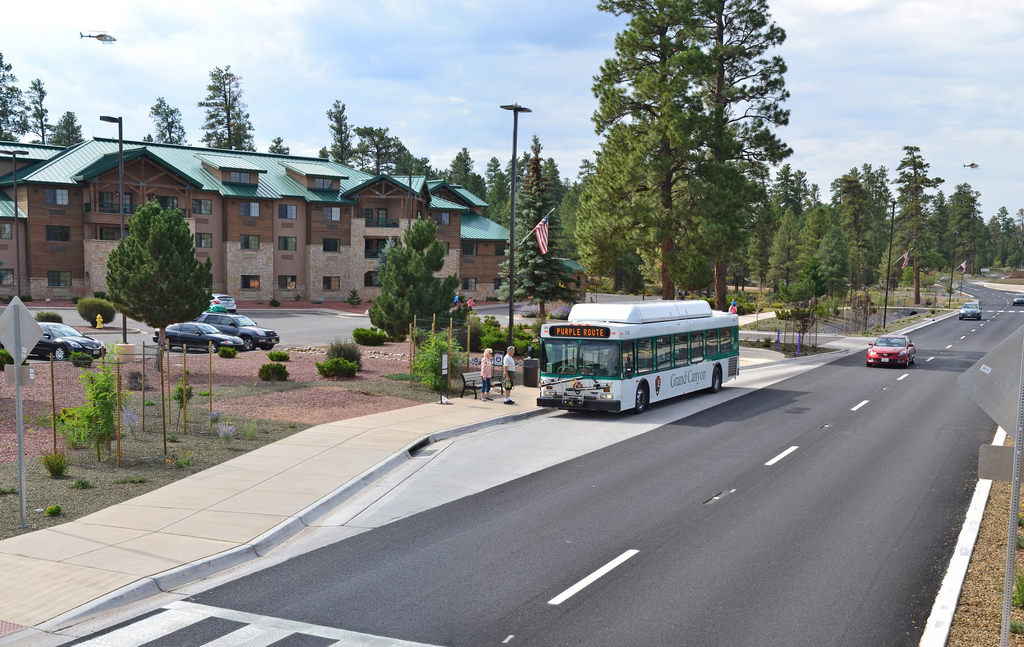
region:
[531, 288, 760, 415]
A commuter bus at a stop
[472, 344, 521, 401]
Two people on sidewalk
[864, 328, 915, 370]
Red car on road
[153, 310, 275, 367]
Two cars parked in parking lot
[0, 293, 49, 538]
Street sign on sidewalk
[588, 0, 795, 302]
Two tall trees near sidewalk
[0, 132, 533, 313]
A large building with green roof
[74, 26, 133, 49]
Helicopter above building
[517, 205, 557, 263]
American flag on lamp post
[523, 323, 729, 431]
a bus stopped at the curb of a road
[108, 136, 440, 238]
a building with a green roof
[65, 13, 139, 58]
a helicopter in the sky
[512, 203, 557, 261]
a flag on a flap pole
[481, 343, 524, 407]
a man and woman standing on a sidewalk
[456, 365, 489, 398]
a bench on a sidewalk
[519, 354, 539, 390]
a garbage can on a sidewalk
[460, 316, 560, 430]
people waiting on a bus stop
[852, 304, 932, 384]
a red car on the road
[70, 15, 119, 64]
a helicopter flying in the sky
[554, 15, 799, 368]
a tall lush green tree on the side of a street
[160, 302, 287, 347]
an SUV parked beside a car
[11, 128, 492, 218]
green roof of a building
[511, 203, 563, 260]
the american flag on a pole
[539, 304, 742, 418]
a white public service bus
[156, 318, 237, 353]
a parked black car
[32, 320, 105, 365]
a parked black car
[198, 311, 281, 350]
a parked grey SUV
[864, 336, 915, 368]
a red car on street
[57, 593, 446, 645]
a white marked pedestrian crosswalk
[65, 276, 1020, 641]
a two lane street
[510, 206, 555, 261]
an American flag on flagpole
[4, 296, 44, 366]
back of a traffic sign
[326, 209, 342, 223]
building has a window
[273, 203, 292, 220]
building has a window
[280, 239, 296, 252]
building has a window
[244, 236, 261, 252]
building has a window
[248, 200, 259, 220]
building has a window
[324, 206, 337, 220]
building has a window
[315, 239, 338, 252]
building has a window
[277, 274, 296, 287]
building has a window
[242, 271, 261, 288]
building has a window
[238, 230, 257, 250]
building has a window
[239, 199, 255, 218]
building has a window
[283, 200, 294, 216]
building has a window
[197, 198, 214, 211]
building has a window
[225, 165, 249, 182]
building has a window